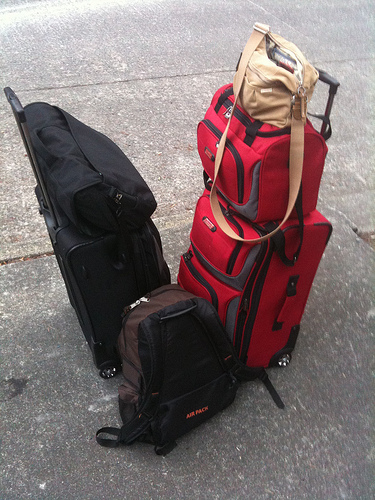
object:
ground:
[0, 1, 375, 500]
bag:
[175, 64, 340, 378]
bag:
[196, 81, 329, 222]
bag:
[116, 283, 225, 443]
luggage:
[3, 85, 171, 379]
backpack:
[95, 296, 284, 454]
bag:
[209, 20, 320, 244]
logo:
[186, 406, 208, 419]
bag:
[23, 101, 157, 239]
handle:
[3, 85, 60, 230]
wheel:
[277, 353, 290, 368]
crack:
[139, 74, 184, 81]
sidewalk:
[0, 0, 375, 500]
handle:
[272, 274, 300, 331]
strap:
[209, 21, 307, 243]